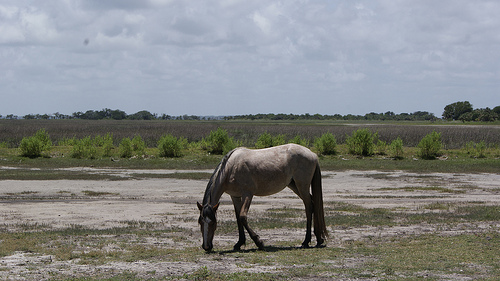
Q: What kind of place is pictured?
A: It is a field.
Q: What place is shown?
A: It is a field.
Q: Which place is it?
A: It is a field.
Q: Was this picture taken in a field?
A: Yes, it was taken in a field.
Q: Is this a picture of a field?
A: Yes, it is showing a field.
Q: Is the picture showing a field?
A: Yes, it is showing a field.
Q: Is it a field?
A: Yes, it is a field.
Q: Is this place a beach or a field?
A: It is a field.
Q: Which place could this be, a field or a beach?
A: It is a field.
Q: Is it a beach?
A: No, it is a field.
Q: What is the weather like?
A: It is cloudy.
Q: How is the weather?
A: It is cloudy.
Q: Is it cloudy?
A: Yes, it is cloudy.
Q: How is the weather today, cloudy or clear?
A: It is cloudy.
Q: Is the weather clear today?
A: No, it is cloudy.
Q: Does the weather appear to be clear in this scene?
A: No, it is cloudy.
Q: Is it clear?
A: No, it is cloudy.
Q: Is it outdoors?
A: Yes, it is outdoors.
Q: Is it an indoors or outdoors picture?
A: It is outdoors.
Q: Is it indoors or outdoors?
A: It is outdoors.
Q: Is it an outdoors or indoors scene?
A: It is outdoors.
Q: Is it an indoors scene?
A: No, it is outdoors.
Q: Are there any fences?
A: No, there are no fences.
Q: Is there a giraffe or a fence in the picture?
A: No, there are no fences or giraffes.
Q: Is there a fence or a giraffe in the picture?
A: No, there are no fences or giraffes.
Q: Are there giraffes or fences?
A: No, there are no fences or giraffes.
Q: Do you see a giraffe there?
A: No, there are no giraffes.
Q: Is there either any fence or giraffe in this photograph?
A: No, there are no giraffes or fences.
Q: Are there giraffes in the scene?
A: No, there are no giraffes.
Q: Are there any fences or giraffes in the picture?
A: No, there are no giraffes or fences.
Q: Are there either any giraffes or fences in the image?
A: No, there are no giraffes or fences.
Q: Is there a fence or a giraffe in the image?
A: No, there are no giraffes or fences.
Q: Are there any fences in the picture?
A: No, there are no fences.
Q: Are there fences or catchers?
A: No, there are no fences or catchers.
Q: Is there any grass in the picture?
A: Yes, there is grass.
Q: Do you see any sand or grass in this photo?
A: Yes, there is grass.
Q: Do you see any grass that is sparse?
A: Yes, there is sparse grass.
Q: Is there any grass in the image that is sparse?
A: Yes, there is grass that is sparse.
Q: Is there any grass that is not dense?
A: Yes, there is sparse grass.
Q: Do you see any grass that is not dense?
A: Yes, there is sparse grass.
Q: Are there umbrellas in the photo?
A: No, there are no umbrellas.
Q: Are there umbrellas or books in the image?
A: No, there are no umbrellas or books.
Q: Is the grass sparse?
A: Yes, the grass is sparse.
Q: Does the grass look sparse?
A: Yes, the grass is sparse.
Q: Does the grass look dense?
A: No, the grass is sparse.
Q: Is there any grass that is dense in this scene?
A: No, there is grass but it is sparse.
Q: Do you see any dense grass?
A: No, there is grass but it is sparse.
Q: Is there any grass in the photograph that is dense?
A: No, there is grass but it is sparse.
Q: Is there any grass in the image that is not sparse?
A: No, there is grass but it is sparse.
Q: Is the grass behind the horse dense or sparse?
A: The grass is sparse.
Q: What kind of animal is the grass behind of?
A: The grass is behind the horse.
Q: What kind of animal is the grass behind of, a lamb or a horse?
A: The grass is behind a horse.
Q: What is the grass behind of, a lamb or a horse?
A: The grass is behind a horse.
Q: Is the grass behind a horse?
A: Yes, the grass is behind a horse.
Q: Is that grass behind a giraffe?
A: No, the grass is behind a horse.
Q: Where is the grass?
A: The grass is on the field.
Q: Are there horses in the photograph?
A: Yes, there is a horse.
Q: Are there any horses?
A: Yes, there is a horse.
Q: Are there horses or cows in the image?
A: Yes, there is a horse.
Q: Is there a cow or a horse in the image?
A: Yes, there is a horse.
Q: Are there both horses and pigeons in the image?
A: No, there is a horse but no pigeons.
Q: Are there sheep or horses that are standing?
A: Yes, the horse is standing.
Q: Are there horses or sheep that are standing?
A: Yes, the horse is standing.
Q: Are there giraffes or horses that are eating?
A: Yes, the horse is eating.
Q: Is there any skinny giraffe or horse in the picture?
A: Yes, there is a skinny horse.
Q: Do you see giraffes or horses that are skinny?
A: Yes, the horse is skinny.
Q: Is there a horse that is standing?
A: Yes, there is a horse that is standing.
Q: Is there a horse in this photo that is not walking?
A: Yes, there is a horse that is standing.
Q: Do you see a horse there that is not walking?
A: Yes, there is a horse that is standing .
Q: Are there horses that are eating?
A: Yes, there is a horse that is eating.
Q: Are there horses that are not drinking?
A: Yes, there is a horse that is eating.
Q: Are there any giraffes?
A: No, there are no giraffes.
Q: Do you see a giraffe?
A: No, there are no giraffes.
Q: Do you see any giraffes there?
A: No, there are no giraffes.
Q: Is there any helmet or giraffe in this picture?
A: No, there are no giraffes or helmets.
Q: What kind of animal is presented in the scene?
A: The animal is a horse.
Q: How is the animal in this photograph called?
A: The animal is a horse.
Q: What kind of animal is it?
A: The animal is a horse.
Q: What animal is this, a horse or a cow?
A: This is a horse.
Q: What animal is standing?
A: The animal is a horse.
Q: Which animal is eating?
A: The animal is a horse.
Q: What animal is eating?
A: The animal is a horse.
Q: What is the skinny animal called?
A: The animal is a horse.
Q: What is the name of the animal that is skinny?
A: The animal is a horse.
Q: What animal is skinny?
A: The animal is a horse.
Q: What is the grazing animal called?
A: The animal is a horse.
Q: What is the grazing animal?
A: The animal is a horse.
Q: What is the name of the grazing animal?
A: The animal is a horse.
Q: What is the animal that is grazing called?
A: The animal is a horse.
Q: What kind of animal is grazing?
A: The animal is a horse.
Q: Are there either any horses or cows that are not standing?
A: No, there is a horse but it is standing.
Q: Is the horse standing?
A: Yes, the horse is standing.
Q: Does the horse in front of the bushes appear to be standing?
A: Yes, the horse is standing.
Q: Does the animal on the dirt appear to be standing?
A: Yes, the horse is standing.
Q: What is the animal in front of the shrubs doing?
A: The horse is standing.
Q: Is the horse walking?
A: No, the horse is standing.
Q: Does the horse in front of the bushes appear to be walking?
A: No, the horse is standing.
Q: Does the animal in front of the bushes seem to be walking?
A: No, the horse is standing.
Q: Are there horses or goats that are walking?
A: No, there is a horse but it is standing.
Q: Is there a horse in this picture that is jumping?
A: No, there is a horse but it is standing.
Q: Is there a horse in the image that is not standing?
A: No, there is a horse but it is standing.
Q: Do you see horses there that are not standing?
A: No, there is a horse but it is standing.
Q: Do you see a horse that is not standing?
A: No, there is a horse but it is standing.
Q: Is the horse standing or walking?
A: The horse is standing.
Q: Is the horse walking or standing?
A: The horse is standing.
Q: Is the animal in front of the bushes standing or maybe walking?
A: The horse is standing.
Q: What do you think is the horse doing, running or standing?
A: The horse is standing.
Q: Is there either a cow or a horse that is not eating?
A: No, there is a horse but it is eating.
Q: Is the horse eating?
A: Yes, the horse is eating.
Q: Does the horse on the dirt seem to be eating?
A: Yes, the horse is eating.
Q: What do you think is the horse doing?
A: The horse is eating.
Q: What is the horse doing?
A: The horse is eating.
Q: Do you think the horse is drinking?
A: No, the horse is eating.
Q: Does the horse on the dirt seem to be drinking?
A: No, the horse is eating.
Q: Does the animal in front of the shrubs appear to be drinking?
A: No, the horse is eating.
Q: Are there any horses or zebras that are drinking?
A: No, there is a horse but it is eating.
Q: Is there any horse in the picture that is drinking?
A: No, there is a horse but it is eating.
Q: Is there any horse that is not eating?
A: No, there is a horse but it is eating.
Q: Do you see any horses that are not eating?
A: No, there is a horse but it is eating.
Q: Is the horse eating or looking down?
A: The horse is eating.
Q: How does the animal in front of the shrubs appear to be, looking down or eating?
A: The horse is eating.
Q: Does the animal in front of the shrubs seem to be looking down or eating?
A: The horse is eating.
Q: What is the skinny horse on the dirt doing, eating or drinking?
A: The horse is eating.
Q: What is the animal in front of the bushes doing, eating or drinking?
A: The horse is eating.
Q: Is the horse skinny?
A: Yes, the horse is skinny.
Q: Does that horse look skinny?
A: Yes, the horse is skinny.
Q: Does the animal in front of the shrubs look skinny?
A: Yes, the horse is skinny.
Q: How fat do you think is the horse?
A: The horse is skinny.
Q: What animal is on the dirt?
A: The animal is a horse.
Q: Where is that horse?
A: The horse is on the dirt.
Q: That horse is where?
A: The horse is on the dirt.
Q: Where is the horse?
A: The horse is on the dirt.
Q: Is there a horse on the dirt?
A: Yes, there is a horse on the dirt.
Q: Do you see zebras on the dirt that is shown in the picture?
A: No, there is a horse on the dirt.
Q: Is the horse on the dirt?
A: Yes, the horse is on the dirt.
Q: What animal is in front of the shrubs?
A: The horse is in front of the shrubs.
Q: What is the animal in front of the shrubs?
A: The animal is a horse.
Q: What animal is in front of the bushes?
A: The animal is a horse.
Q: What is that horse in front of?
A: The horse is in front of the shrubs.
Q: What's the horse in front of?
A: The horse is in front of the shrubs.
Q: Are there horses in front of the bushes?
A: Yes, there is a horse in front of the bushes.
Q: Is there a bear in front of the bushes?
A: No, there is a horse in front of the bushes.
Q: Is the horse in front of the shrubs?
A: Yes, the horse is in front of the shrubs.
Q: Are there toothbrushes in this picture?
A: No, there are no toothbrushes.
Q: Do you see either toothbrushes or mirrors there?
A: No, there are no toothbrushes or mirrors.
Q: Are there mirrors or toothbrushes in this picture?
A: No, there are no toothbrushes or mirrors.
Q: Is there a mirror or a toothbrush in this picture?
A: No, there are no toothbrushes or mirrors.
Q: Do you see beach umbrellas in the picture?
A: No, there are no beach umbrellas.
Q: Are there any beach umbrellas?
A: No, there are no beach umbrellas.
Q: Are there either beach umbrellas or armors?
A: No, there are no beach umbrellas or armors.